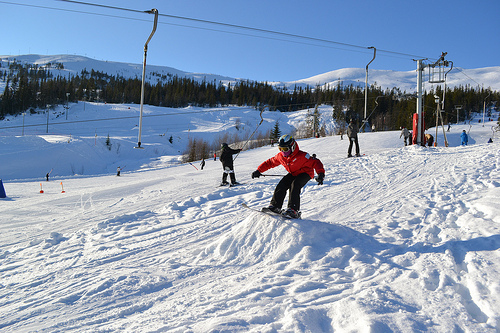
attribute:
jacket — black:
[209, 126, 247, 180]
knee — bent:
[271, 175, 286, 198]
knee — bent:
[286, 175, 301, 204]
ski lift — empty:
[131, 7, 161, 157]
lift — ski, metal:
[421, 57, 453, 87]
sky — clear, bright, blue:
[0, 1, 497, 86]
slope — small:
[95, 77, 358, 207]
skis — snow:
[249, 189, 295, 224]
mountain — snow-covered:
[2, 53, 498, 90]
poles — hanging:
[128, 7, 163, 148]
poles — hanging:
[358, 45, 376, 137]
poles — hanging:
[438, 55, 455, 115]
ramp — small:
[194, 205, 365, 263]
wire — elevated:
[61, 0, 429, 68]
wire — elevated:
[6, 1, 387, 60]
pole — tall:
[407, 56, 424, 152]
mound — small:
[216, 209, 376, 267]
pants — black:
[261, 171, 311, 219]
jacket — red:
[254, 151, 327, 177]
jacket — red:
[254, 153, 329, 181]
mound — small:
[202, 202, 368, 272]